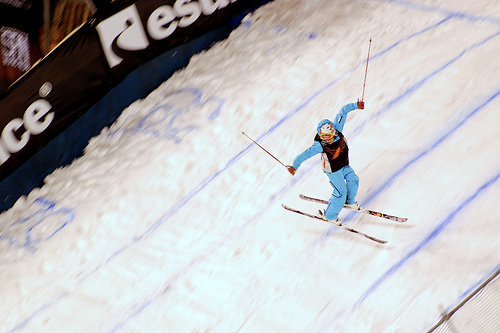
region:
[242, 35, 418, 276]
The person is skiing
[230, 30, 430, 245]
The person in blue ski pants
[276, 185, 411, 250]
The person on skis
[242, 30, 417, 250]
The person holding ski poles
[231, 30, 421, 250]
The person wearing a helmet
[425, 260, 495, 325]
The net beside the snow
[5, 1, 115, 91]
The net beside the snow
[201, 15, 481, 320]
Blue lines in the snow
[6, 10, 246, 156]
The white writing on a black sign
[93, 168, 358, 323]
The snow is white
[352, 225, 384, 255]
edge of a skateboard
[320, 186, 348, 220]
part of a trouser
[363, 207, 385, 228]
edge of a skater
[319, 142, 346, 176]
part of a jacket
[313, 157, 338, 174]
edge of a jacket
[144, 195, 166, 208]
Small patch of the snow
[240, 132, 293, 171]
Right red ski pole of skier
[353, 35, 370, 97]
Left red ski pole of the skier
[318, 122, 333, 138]
White helmet of the skier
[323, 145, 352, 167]
Black and orange suit of the skier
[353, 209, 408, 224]
Left ski of the skier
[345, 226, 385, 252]
Right ski of the skier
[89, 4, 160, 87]
Company logo on pad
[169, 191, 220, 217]
Blue line in the snow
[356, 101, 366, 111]
Red glove of the skier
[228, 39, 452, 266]
a person skiing down a hill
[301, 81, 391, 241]
a person wearing a blue ski suit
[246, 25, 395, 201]
a person holding ski poles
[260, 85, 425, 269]
a person wearing skiis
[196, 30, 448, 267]
a person holding ski poles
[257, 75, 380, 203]
a person wearing red gloves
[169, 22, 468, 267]
blue lines painted in the snow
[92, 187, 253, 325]
tracks in the snow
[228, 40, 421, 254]
a person turned sideways on skis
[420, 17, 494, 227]
four blue lines painted in the snow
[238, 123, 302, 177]
The left ski pole in the skier's hand.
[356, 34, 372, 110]
The right ski pole in the skier's hand.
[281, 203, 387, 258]
The left ski the skier is wearing.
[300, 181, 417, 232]
The right ski the skier is wearing.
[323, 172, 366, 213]
The blue pants the skier is wearing.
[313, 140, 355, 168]
The black vest the skier has on.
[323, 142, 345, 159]
The orange design on the skier's vest.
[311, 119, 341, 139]
The white helmet on the skier's head.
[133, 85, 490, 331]
The snow area the skier is skiing.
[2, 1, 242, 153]
The black banner with white lettering on it.